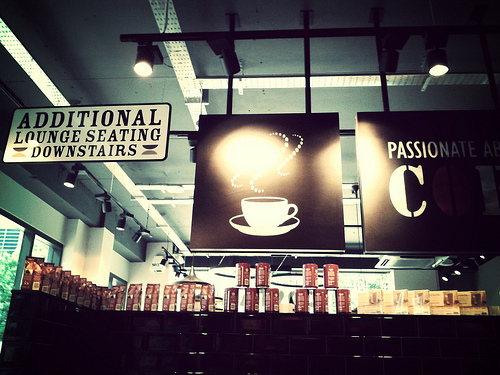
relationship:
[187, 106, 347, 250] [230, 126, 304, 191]
sign showing dots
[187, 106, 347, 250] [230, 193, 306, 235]
sign showing coffee cup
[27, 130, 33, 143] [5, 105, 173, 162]
letter o on sign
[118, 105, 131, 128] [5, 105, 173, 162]
letter n on sign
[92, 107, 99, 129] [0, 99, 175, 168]
letter i on sign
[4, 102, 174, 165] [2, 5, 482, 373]
sign in restaurant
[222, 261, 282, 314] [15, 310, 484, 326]
cans on ledge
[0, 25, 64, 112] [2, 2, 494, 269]
beams on ceiling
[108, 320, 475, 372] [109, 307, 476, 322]
tile under shelf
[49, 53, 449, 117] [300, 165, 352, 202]
ceiling of large room with beams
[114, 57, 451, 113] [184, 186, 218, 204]
hanging lights facing downwards and shining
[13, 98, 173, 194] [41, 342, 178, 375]
oblong sign telling customers where to find more seats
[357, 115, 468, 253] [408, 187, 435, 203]
dark sign with letter of alphabet and a word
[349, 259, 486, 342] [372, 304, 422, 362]
packages displayed in a repeated pattern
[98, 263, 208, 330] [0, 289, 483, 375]
packages aligned on ledge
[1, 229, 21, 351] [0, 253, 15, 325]
window showing a tall building and a trees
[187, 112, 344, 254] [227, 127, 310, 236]
poster has coffee image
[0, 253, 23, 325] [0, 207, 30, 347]
trees seen through window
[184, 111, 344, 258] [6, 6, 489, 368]
image takes place indoors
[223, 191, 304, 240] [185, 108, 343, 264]
coffee cup on banner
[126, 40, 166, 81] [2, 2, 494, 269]
light fixture illuminated on ceiling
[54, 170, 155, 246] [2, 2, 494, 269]
lights on ceiling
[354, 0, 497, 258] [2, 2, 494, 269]
advertising board hanging from ceiling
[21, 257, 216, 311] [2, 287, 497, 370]
coffee bags on counter